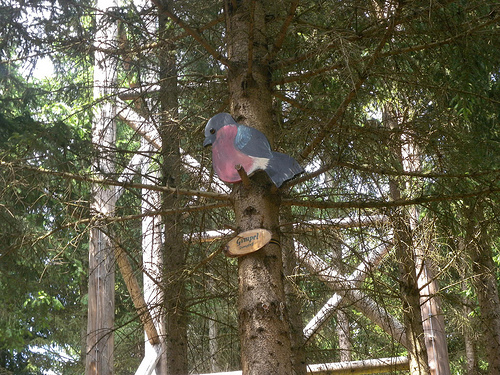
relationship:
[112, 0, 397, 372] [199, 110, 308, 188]
pine tree with wood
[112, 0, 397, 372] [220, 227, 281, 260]
pine tree with wood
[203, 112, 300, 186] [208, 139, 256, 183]
bird with belly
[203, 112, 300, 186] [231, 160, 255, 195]
bird on branch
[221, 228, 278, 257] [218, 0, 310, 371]
sign attached to tree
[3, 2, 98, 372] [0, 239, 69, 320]
tree with leaves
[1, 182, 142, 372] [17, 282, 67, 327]
tree with leaves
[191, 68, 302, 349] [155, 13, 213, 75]
tree with leaves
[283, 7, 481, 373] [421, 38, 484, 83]
tree with leaves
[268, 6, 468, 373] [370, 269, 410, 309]
tree with leaves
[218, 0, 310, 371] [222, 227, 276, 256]
tree with sign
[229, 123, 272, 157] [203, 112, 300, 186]
wing of bird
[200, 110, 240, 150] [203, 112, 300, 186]
head of bird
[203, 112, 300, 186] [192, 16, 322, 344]
bird in tree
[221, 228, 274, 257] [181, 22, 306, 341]
sign in tree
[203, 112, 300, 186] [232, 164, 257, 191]
bird on perch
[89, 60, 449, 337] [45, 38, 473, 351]
framework in forest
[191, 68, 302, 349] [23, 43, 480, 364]
tree in forest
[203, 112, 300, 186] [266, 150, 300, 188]
bird has tail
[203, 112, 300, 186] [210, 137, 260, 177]
bird has belly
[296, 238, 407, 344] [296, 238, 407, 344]
cross form cross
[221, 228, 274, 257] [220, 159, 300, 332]
sign on tree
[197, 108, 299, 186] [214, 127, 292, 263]
bird nailed to trunk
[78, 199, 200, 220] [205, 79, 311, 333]
branch sticking off tree